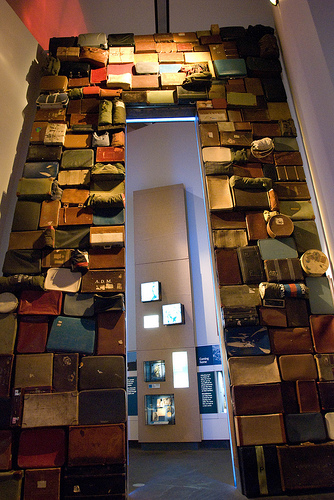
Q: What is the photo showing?
A: It is showing a display.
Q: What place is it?
A: It is a display.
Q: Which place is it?
A: It is a display.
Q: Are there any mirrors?
A: Yes, there is a mirror.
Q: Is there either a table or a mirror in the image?
A: Yes, there is a mirror.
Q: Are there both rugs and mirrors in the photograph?
A: No, there is a mirror but no rugs.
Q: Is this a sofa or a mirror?
A: This is a mirror.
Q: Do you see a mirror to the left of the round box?
A: Yes, there is a mirror to the left of the box.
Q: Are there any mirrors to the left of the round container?
A: Yes, there is a mirror to the left of the box.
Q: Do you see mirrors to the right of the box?
A: No, the mirror is to the left of the box.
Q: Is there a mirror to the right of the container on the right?
A: No, the mirror is to the left of the box.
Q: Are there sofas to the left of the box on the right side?
A: No, there is a mirror to the left of the box.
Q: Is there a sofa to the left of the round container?
A: No, there is a mirror to the left of the box.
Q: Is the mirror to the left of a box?
A: Yes, the mirror is to the left of a box.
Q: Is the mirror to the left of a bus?
A: No, the mirror is to the left of a box.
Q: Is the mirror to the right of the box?
A: No, the mirror is to the left of the box.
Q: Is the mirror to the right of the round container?
A: No, the mirror is to the left of the box.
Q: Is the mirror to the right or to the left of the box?
A: The mirror is to the left of the box.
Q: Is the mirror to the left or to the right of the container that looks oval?
A: The mirror is to the left of the box.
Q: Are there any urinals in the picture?
A: No, there are no urinals.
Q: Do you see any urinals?
A: No, there are no urinals.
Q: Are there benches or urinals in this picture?
A: No, there are no urinals or benches.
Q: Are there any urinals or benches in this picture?
A: No, there are no urinals or benches.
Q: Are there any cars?
A: No, there are no cars.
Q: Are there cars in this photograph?
A: No, there are no cars.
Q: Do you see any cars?
A: No, there are no cars.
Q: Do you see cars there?
A: No, there are no cars.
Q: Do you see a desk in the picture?
A: No, there are no desks.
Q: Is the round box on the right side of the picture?
A: Yes, the box is on the right of the image.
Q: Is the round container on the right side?
A: Yes, the box is on the right of the image.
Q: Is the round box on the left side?
A: No, the box is on the right of the image.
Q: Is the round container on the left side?
A: No, the box is on the right of the image.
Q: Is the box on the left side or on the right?
A: The box is on the right of the image.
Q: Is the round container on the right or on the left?
A: The box is on the right of the image.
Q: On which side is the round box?
A: The box is on the right of the image.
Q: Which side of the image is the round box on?
A: The box is on the right of the image.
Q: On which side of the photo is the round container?
A: The box is on the right of the image.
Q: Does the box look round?
A: Yes, the box is round.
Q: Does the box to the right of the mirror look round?
A: Yes, the box is round.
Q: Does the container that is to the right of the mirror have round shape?
A: Yes, the box is round.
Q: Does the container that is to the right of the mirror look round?
A: Yes, the box is round.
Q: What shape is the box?
A: The box is round.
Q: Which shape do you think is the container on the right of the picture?
A: The box is round.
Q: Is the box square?
A: No, the box is round.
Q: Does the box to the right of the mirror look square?
A: No, the box is round.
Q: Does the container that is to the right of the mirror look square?
A: No, the box is round.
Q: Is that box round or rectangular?
A: The box is round.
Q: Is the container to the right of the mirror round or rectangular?
A: The box is round.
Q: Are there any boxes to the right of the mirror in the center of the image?
A: Yes, there is a box to the right of the mirror.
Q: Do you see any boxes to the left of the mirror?
A: No, the box is to the right of the mirror.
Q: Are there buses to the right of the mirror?
A: No, there is a box to the right of the mirror.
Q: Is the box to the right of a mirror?
A: Yes, the box is to the right of a mirror.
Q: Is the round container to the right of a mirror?
A: Yes, the box is to the right of a mirror.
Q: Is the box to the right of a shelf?
A: No, the box is to the right of a mirror.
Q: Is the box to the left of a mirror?
A: No, the box is to the right of a mirror.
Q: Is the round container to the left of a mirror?
A: No, the box is to the right of a mirror.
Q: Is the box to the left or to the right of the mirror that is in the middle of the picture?
A: The box is to the right of the mirror.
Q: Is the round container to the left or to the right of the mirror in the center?
A: The box is to the right of the mirror.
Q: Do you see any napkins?
A: No, there are no napkins.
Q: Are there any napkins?
A: No, there are no napkins.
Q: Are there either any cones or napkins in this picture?
A: No, there are no napkins or cones.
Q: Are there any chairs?
A: No, there are no chairs.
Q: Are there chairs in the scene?
A: No, there are no chairs.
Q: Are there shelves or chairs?
A: No, there are no chairs or shelves.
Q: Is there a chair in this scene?
A: No, there are no chairs.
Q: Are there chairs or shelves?
A: No, there are no chairs or shelves.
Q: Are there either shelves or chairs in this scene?
A: No, there are no chairs or shelves.